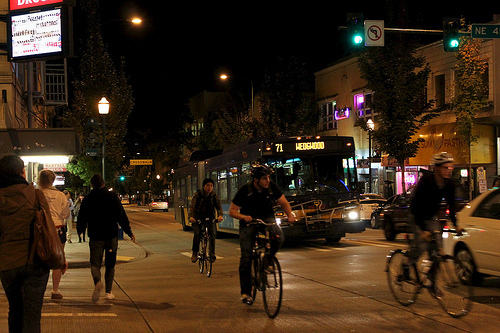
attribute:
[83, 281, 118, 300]
shoes — white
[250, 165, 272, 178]
helmet — black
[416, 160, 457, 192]
ground — white, black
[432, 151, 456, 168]
helmet — silver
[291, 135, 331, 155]
sign — digital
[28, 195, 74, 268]
purse — brown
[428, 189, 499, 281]
car — white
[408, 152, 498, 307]
car — white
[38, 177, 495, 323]
scene — night time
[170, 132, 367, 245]
bus — big, dark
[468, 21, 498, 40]
street sign — green, white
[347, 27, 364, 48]
light — green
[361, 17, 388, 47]
sign — red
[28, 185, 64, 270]
bag — brown, leather